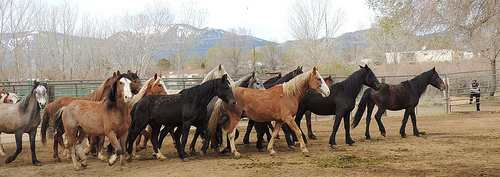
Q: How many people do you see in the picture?
A: 1.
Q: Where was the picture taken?
A: A farm.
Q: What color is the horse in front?
A: Brown.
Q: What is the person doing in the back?
A: Watching the horses.